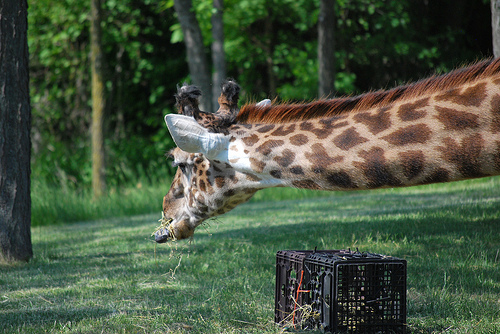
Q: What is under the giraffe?
A: A black crate.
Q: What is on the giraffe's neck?
A: Spots.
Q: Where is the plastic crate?
A: Below the giraffes neck.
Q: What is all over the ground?
A: Grass.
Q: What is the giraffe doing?
A: Eating.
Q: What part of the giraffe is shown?
A: Head.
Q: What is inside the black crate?
A: Food.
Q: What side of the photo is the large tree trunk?
A: Left.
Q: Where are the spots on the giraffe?
A: On the fur.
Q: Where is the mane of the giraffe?
A: Back of the neck.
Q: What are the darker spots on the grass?
A: Shadows from the trees.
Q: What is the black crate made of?
A: Plastic.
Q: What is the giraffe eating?
A: Straw.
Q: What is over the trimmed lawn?
A: Shade.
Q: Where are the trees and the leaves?
A: In backgreound.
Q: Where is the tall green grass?
A: Near tree.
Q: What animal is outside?
A: Giraffe.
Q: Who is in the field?
A: Giraffe.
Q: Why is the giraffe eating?
A: Hungry.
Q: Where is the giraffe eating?
A: In field.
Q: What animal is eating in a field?
A: Giraffe.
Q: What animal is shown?
A: Giraffe.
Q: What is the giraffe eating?
A: Grass.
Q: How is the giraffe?
A: Brown and white.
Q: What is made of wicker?
A: The basket.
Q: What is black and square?
A: The basket.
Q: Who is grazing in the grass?
A: The giraffe.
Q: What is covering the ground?
A: Grass.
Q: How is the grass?
A: Green and thick.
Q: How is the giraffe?
A: Brown and yellow.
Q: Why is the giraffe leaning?
A: It's eating.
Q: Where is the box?
A: Under the giraffe.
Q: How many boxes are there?
A: One.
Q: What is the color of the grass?
A: Green.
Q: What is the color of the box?
A: Black.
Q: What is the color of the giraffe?
A: Brown.